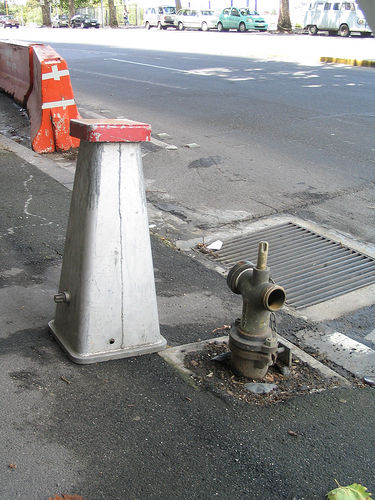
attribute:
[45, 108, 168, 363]
cone — silver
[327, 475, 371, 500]
leaf — dead, green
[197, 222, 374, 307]
storm grate — grey, metal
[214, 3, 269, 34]
car — green, small, seafoam green, mint green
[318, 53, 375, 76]
stripe — yellow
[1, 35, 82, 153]
barriers — orange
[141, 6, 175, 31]
utility vehicle — white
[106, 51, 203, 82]
stripe — white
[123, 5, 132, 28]
person — walking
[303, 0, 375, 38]
bus — white, parked, blue, old style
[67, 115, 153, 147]
top — red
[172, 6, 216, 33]
station wagon — white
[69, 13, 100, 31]
car — black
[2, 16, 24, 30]
car — red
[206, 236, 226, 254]
paper — white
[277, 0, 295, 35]
tree trunk — large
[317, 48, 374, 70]
curb — yellow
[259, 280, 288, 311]
hose attachment — rusted